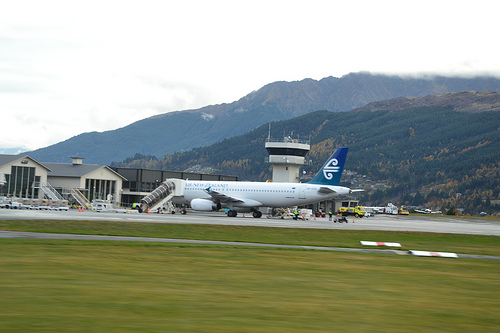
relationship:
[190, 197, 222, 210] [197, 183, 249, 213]
engine under wing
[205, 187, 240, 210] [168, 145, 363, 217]
wing on plane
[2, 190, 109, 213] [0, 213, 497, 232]
vehicles on tarmac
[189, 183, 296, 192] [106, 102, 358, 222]
windows on plane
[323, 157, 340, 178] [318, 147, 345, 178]
design on tail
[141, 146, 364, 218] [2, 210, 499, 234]
plane on tarmac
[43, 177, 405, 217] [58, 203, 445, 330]
cones on ground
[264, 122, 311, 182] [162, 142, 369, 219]
control tower behind plane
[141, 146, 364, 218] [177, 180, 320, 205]
plane has side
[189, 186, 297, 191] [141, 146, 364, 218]
windows on plane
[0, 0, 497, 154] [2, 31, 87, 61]
sky has cloud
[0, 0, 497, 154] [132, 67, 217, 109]
sky has cloud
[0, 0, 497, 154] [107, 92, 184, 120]
sky has cloud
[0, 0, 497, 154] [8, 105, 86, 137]
sky has cloud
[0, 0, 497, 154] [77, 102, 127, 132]
sky has cloud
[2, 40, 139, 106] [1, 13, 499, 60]
clouds in sky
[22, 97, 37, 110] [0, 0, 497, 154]
cloud in sky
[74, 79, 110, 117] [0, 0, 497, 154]
cloud in sky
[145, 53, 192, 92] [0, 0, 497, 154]
cloud in sky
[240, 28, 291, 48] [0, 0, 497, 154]
cloud in sky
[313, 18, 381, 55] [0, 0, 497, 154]
cloud in sky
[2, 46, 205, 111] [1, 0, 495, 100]
clouds in sky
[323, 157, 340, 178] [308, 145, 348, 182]
design on tail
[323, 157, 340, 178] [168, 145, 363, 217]
design on plane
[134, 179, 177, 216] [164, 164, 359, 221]
stairway leads to plane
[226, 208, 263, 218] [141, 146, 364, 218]
wheels under plane